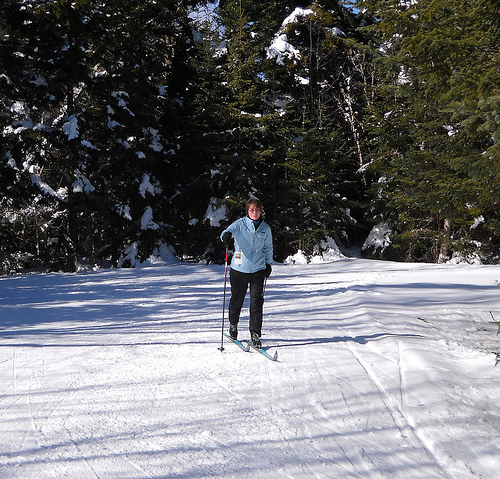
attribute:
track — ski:
[343, 331, 450, 477]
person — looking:
[216, 182, 283, 375]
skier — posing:
[216, 197, 278, 347]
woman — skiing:
[218, 197, 275, 348]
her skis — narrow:
[188, 312, 311, 344]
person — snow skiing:
[219, 197, 274, 348]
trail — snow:
[14, 277, 487, 477]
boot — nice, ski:
[228, 321, 238, 341]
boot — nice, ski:
[248, 332, 261, 349]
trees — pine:
[3, 2, 497, 255]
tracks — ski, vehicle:
[340, 331, 439, 451]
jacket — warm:
[218, 215, 273, 274]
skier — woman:
[205, 306, 287, 371]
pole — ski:
[216, 242, 228, 354]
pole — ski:
[260, 264, 268, 324]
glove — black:
[215, 231, 234, 244]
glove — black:
[265, 261, 273, 272]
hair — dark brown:
[245, 201, 265, 219]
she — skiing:
[211, 193, 290, 364]